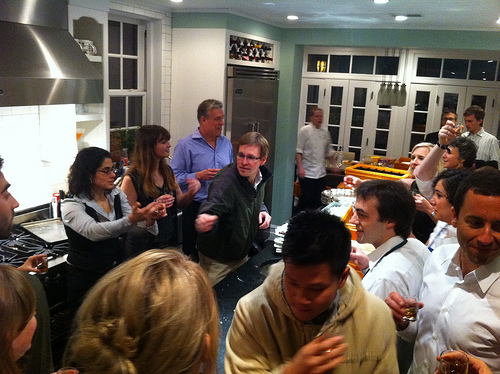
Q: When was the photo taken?
A: Nighttime.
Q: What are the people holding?
A: Shot glasses.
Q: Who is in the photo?
A: People.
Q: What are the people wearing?
A: Clothes.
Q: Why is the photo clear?
A: The area is lit.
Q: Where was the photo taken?
A: In a kitchen.